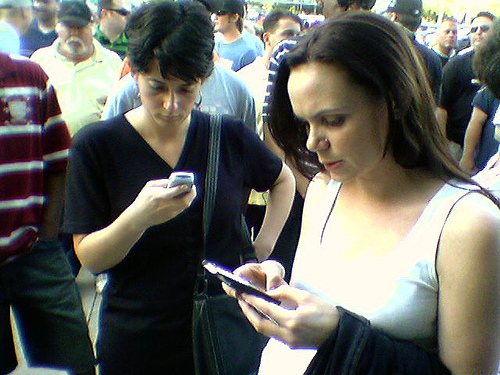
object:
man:
[233, 12, 309, 119]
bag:
[180, 113, 267, 374]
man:
[1, 0, 56, 59]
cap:
[0, 1, 33, 13]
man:
[0, 47, 92, 375]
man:
[22, 8, 131, 137]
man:
[93, 0, 133, 58]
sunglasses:
[100, 5, 130, 16]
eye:
[321, 108, 348, 130]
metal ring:
[187, 275, 210, 294]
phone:
[169, 171, 194, 193]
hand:
[127, 177, 199, 233]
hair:
[119, 0, 218, 88]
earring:
[194, 92, 204, 106]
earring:
[135, 83, 140, 99]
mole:
[324, 139, 329, 143]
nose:
[306, 122, 329, 153]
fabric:
[64, 120, 281, 373]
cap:
[50, 0, 90, 27]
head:
[266, 11, 430, 191]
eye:
[148, 78, 166, 91]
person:
[63, 0, 295, 375]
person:
[213, 16, 500, 375]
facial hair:
[59, 36, 86, 55]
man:
[212, 1, 261, 64]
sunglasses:
[210, 10, 225, 15]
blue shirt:
[211, 40, 263, 71]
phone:
[198, 257, 283, 305]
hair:
[266, 8, 498, 205]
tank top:
[254, 169, 474, 375]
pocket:
[26, 231, 74, 291]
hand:
[30, 231, 65, 269]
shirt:
[232, 57, 266, 134]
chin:
[322, 166, 348, 180]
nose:
[161, 85, 181, 112]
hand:
[235, 287, 339, 346]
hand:
[223, 260, 285, 298]